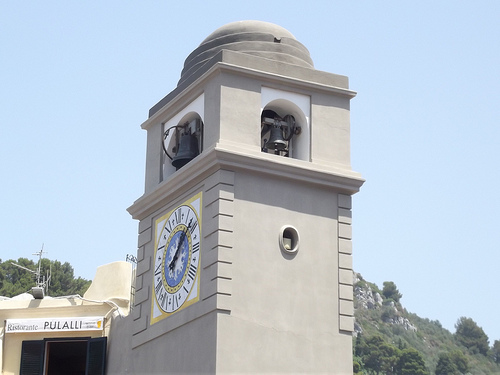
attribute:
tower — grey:
[104, 23, 366, 374]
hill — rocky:
[354, 256, 487, 374]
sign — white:
[22, 307, 99, 338]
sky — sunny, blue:
[18, 22, 115, 157]